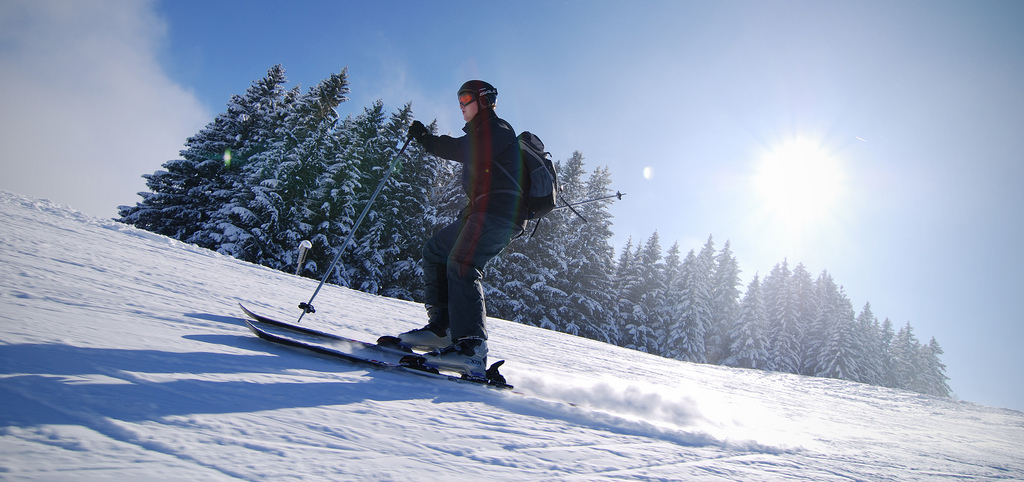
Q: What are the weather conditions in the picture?
A: It is clear.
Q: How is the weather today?
A: It is clear.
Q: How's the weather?
A: It is clear.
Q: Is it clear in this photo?
A: Yes, it is clear.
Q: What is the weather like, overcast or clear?
A: It is clear.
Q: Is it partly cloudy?
A: No, it is clear.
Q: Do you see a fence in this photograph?
A: No, there are no fences.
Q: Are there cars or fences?
A: No, there are no fences or cars.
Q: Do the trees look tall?
A: Yes, the trees are tall.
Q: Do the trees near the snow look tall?
A: Yes, the trees are tall.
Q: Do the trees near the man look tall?
A: Yes, the trees are tall.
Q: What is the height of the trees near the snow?
A: The trees are tall.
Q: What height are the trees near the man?
A: The trees are tall.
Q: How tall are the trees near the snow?
A: The trees are tall.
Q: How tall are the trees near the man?
A: The trees are tall.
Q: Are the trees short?
A: No, the trees are tall.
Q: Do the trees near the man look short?
A: No, the trees are tall.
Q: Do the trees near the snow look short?
A: No, the trees are tall.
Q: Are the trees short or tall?
A: The trees are tall.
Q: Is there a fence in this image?
A: No, there are no fences.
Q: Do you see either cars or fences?
A: No, there are no fences or cars.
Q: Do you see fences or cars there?
A: No, there are no fences or cars.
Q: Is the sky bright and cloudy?
A: No, the sky is bright but clear.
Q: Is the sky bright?
A: Yes, the sky is bright.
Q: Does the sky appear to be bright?
A: Yes, the sky is bright.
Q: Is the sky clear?
A: Yes, the sky is clear.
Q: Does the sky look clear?
A: Yes, the sky is clear.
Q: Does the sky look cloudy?
A: No, the sky is clear.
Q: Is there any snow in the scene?
A: Yes, there is snow.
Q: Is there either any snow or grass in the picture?
A: Yes, there is snow.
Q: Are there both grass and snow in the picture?
A: No, there is snow but no grass.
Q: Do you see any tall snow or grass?
A: Yes, there is tall snow.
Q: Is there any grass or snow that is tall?
A: Yes, the snow is tall.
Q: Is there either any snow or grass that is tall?
A: Yes, the snow is tall.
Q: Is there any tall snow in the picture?
A: Yes, there is tall snow.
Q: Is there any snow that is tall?
A: Yes, there is snow that is tall.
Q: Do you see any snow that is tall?
A: Yes, there is snow that is tall.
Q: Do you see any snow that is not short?
A: Yes, there is tall snow.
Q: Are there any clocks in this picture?
A: No, there are no clocks.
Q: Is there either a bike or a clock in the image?
A: No, there are no clocks or bikes.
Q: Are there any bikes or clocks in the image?
A: No, there are no clocks or bikes.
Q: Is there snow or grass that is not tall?
A: No, there is snow but it is tall.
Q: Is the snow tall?
A: Yes, the snow is tall.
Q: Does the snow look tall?
A: Yes, the snow is tall.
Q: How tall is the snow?
A: The snow is tall.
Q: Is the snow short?
A: No, the snow is tall.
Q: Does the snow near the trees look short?
A: No, the snow is tall.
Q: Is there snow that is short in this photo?
A: No, there is snow but it is tall.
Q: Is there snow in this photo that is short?
A: No, there is snow but it is tall.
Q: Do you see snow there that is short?
A: No, there is snow but it is tall.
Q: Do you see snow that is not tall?
A: No, there is snow but it is tall.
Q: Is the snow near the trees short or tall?
A: The snow is tall.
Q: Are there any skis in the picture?
A: Yes, there are skis.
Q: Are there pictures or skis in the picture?
A: Yes, there are skis.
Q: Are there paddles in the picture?
A: No, there are no paddles.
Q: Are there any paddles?
A: No, there are no paddles.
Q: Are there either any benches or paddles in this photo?
A: No, there are no paddles or benches.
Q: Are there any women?
A: No, there are no women.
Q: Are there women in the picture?
A: No, there are no women.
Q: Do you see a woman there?
A: No, there are no women.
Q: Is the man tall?
A: Yes, the man is tall.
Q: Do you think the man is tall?
A: Yes, the man is tall.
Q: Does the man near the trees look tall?
A: Yes, the man is tall.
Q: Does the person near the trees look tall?
A: Yes, the man is tall.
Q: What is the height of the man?
A: The man is tall.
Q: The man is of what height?
A: The man is tall.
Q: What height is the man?
A: The man is tall.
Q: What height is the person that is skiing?
A: The man is tall.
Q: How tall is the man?
A: The man is tall.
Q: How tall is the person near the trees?
A: The man is tall.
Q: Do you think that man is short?
A: No, the man is tall.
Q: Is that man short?
A: No, the man is tall.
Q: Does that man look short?
A: No, the man is tall.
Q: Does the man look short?
A: No, the man is tall.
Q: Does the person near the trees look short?
A: No, the man is tall.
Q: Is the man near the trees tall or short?
A: The man is tall.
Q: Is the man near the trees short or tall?
A: The man is tall.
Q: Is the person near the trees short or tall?
A: The man is tall.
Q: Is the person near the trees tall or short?
A: The man is tall.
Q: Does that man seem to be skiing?
A: Yes, the man is skiing.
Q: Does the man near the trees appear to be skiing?
A: Yes, the man is skiing.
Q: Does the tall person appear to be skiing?
A: Yes, the man is skiing.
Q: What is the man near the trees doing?
A: The man is skiing.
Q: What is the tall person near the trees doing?
A: The man is skiing.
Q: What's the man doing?
A: The man is skiing.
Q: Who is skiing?
A: The man is skiing.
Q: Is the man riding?
A: No, the man is skiing.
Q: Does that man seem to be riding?
A: No, the man is skiing.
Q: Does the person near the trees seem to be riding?
A: No, the man is skiing.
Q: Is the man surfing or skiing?
A: The man is skiing.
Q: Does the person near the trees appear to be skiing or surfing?
A: The man is skiing.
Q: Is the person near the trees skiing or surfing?
A: The man is skiing.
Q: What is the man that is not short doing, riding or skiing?
A: The man is skiing.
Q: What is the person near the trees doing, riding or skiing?
A: The man is skiing.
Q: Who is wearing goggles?
A: The man is wearing goggles.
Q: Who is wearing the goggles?
A: The man is wearing goggles.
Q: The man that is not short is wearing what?
A: The man is wearing goggles.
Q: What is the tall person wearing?
A: The man is wearing goggles.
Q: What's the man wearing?
A: The man is wearing goggles.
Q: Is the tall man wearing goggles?
A: Yes, the man is wearing goggles.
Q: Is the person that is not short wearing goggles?
A: Yes, the man is wearing goggles.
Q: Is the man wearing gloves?
A: No, the man is wearing goggles.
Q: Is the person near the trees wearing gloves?
A: No, the man is wearing goggles.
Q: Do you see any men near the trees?
A: Yes, there is a man near the trees.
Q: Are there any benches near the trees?
A: No, there is a man near the trees.